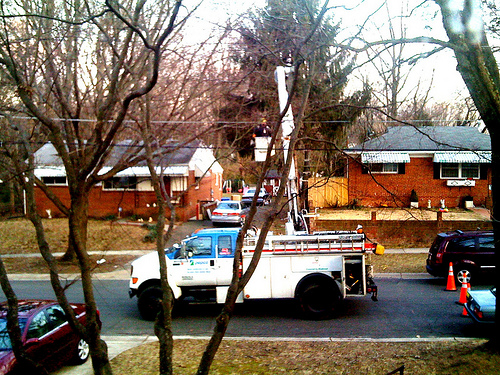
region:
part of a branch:
[246, 255, 258, 272]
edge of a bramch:
[202, 328, 225, 354]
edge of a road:
[409, 330, 428, 344]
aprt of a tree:
[206, 290, 254, 346]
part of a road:
[399, 291, 422, 322]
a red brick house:
[342, 127, 479, 222]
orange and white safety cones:
[436, 249, 488, 326]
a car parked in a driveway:
[22, 289, 108, 374]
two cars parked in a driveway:
[212, 182, 267, 229]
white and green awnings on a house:
[356, 148, 493, 173]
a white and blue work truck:
[112, 212, 389, 339]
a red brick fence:
[303, 211, 485, 249]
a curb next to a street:
[153, 329, 447, 354]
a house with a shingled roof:
[361, 120, 481, 192]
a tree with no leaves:
[36, 27, 200, 264]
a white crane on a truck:
[114, 59, 390, 324]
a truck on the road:
[116, 208, 413, 352]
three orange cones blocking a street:
[413, 245, 479, 340]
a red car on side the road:
[0, 282, 125, 371]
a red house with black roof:
[14, 128, 239, 228]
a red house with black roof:
[300, 118, 495, 209]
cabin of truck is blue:
[127, 220, 285, 295]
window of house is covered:
[157, 171, 197, 198]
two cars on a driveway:
[201, 170, 282, 230]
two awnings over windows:
[354, 145, 491, 181]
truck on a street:
[121, 223, 390, 331]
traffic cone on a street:
[440, 257, 460, 294]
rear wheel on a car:
[70, 333, 92, 368]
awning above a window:
[356, 147, 412, 167]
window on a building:
[429, 158, 490, 183]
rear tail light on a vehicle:
[431, 235, 451, 262]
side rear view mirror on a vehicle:
[176, 232, 191, 262]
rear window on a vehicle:
[214, 200, 241, 212]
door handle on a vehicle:
[205, 256, 217, 268]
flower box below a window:
[443, 177, 478, 193]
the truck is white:
[136, 226, 401, 328]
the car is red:
[0, 290, 103, 368]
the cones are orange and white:
[438, 260, 470, 305]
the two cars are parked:
[207, 181, 299, 223]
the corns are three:
[421, 260, 478, 316]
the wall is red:
[363, 150, 497, 212]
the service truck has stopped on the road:
[133, 229, 378, 321]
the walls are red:
[37, 190, 175, 222]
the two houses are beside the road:
[33, 123, 497, 233]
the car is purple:
[426, 227, 498, 291]